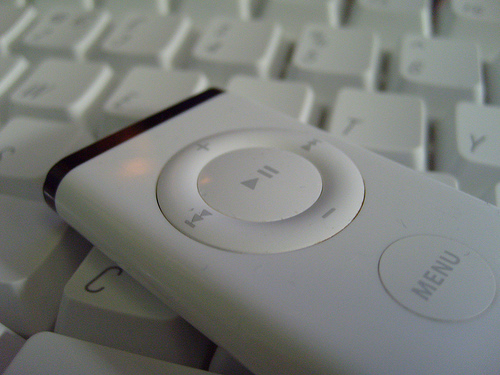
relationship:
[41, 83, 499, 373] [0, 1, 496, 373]
controler on keyboard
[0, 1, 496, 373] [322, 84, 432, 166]
keyboard has key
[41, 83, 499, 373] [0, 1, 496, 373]
controler on top of keyboard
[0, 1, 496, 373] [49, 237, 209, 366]
keyboard has button